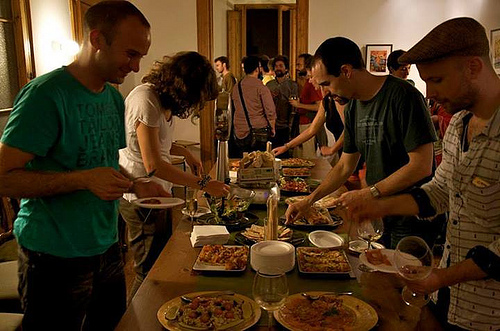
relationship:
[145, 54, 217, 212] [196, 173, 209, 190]
lady wearing bracelet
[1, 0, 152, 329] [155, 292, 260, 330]
people eating food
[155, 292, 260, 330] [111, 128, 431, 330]
food on buffet table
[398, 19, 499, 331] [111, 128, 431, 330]
people at a buffet table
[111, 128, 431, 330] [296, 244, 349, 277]
buffet table of food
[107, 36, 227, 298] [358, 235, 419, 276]
lady getting food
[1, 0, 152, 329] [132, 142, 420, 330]
people at a buffet table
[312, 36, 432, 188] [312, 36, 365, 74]
man has dark hair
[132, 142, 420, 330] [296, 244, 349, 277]
buffet table has plenty food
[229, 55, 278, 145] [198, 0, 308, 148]
people in doorway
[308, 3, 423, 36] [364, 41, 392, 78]
wall has paintings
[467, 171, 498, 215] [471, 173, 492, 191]
shirt pocket has cigarettes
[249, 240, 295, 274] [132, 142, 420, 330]
paper plates stacked on table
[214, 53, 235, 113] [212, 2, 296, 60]
people in or room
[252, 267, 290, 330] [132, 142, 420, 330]
goblet on buffet table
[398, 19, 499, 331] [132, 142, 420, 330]
people getting ready to pig out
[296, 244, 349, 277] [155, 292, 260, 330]
serving dish has plenty food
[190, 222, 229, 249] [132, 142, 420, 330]
paper napkins are on buffet table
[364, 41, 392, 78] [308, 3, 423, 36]
picture displayed on wall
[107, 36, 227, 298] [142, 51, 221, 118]
lady has wavy hair